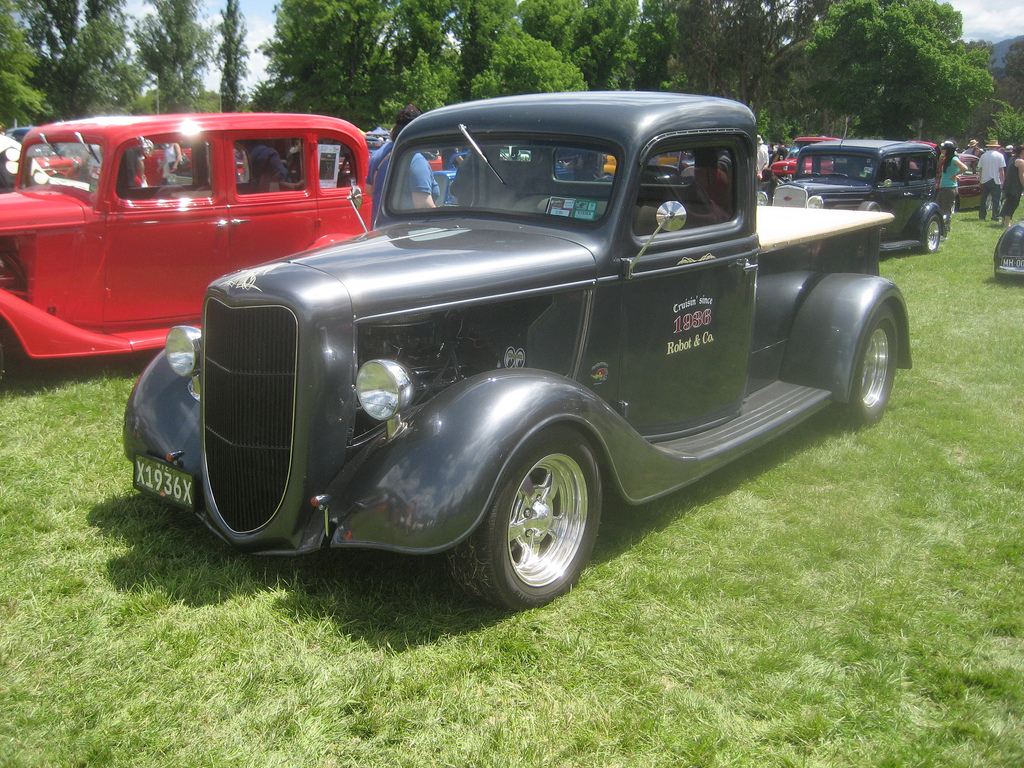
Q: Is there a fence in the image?
A: No, there are no fences.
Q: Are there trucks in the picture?
A: Yes, there is a truck.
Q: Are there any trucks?
A: Yes, there is a truck.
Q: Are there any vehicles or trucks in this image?
A: Yes, there is a truck.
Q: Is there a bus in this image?
A: No, there are no buses.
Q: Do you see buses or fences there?
A: No, there are no buses or fences.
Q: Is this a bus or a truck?
A: This is a truck.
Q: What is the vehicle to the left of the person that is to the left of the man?
A: The vehicle is a truck.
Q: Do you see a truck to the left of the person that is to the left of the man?
A: Yes, there is a truck to the left of the person.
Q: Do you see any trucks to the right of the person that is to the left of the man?
A: No, the truck is to the left of the person.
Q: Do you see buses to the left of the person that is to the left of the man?
A: No, there is a truck to the left of the person.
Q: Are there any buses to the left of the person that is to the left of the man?
A: No, there is a truck to the left of the person.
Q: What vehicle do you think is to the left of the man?
A: The vehicle is a truck.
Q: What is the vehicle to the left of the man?
A: The vehicle is a truck.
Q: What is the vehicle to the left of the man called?
A: The vehicle is a truck.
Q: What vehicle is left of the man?
A: The vehicle is a truck.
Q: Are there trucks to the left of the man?
A: Yes, there is a truck to the left of the man.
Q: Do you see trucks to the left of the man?
A: Yes, there is a truck to the left of the man.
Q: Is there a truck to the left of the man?
A: Yes, there is a truck to the left of the man.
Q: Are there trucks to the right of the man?
A: No, the truck is to the left of the man.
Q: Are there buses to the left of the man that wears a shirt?
A: No, there is a truck to the left of the man.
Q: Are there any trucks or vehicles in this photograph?
A: Yes, there is a truck.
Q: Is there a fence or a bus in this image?
A: No, there are no fences or buses.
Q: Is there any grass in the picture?
A: Yes, there is grass.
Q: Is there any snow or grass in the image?
A: Yes, there is grass.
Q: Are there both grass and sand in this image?
A: No, there is grass but no sand.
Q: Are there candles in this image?
A: No, there are no candles.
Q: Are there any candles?
A: No, there are no candles.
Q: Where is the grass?
A: The grass is on the ground.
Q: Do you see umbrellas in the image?
A: No, there are no umbrellas.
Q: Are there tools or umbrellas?
A: No, there are no umbrellas or tools.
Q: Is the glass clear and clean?
A: Yes, the glass is clear and clean.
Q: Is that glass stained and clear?
A: No, the glass is clear but clean.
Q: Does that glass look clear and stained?
A: No, the glass is clear but clean.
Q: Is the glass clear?
A: Yes, the glass is clear.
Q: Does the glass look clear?
A: Yes, the glass is clear.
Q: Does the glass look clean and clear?
A: Yes, the glass is clean and clear.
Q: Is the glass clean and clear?
A: Yes, the glass is clean and clear.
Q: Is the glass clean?
A: Yes, the glass is clean.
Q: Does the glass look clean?
A: Yes, the glass is clean.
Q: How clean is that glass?
A: The glass is clean.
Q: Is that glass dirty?
A: No, the glass is clean.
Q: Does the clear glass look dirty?
A: No, the glass is clean.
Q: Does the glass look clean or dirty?
A: The glass is clean.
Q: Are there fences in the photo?
A: No, there are no fences.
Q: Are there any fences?
A: No, there are no fences.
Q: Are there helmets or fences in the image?
A: No, there are no fences or helmets.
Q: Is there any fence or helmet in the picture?
A: No, there are no fences or helmets.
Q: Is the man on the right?
A: Yes, the man is on the right of the image.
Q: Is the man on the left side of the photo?
A: No, the man is on the right of the image.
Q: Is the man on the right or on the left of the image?
A: The man is on the right of the image.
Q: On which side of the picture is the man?
A: The man is on the right of the image.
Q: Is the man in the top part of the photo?
A: Yes, the man is in the top of the image.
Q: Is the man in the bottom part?
A: No, the man is in the top of the image.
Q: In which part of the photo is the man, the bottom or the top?
A: The man is in the top of the image.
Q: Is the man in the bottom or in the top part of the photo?
A: The man is in the top of the image.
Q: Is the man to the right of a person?
A: Yes, the man is to the right of a person.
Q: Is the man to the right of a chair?
A: No, the man is to the right of a person.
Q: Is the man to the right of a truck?
A: Yes, the man is to the right of a truck.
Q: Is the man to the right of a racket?
A: No, the man is to the right of a truck.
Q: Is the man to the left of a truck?
A: No, the man is to the right of a truck.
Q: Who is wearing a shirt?
A: The man is wearing a shirt.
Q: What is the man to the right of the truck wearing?
A: The man is wearing a shirt.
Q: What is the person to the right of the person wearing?
A: The man is wearing a shirt.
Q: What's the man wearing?
A: The man is wearing a shirt.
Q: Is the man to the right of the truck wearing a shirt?
A: Yes, the man is wearing a shirt.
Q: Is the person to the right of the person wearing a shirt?
A: Yes, the man is wearing a shirt.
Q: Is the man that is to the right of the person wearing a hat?
A: No, the man is wearing a shirt.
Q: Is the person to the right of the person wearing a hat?
A: No, the man is wearing a shirt.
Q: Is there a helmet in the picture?
A: No, there are no helmets.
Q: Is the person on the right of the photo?
A: Yes, the person is on the right of the image.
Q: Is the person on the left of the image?
A: No, the person is on the right of the image.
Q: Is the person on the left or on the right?
A: The person is on the right of the image.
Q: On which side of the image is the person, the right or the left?
A: The person is on the right of the image.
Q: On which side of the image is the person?
A: The person is on the right of the image.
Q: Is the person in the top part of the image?
A: Yes, the person is in the top of the image.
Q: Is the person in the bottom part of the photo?
A: No, the person is in the top of the image.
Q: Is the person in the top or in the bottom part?
A: The person is in the top of the image.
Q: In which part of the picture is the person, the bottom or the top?
A: The person is in the top of the image.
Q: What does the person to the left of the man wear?
A: The person wears a shirt.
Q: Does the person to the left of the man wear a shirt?
A: Yes, the person wears a shirt.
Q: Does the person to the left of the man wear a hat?
A: No, the person wears a shirt.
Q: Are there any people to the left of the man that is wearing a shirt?
A: Yes, there is a person to the left of the man.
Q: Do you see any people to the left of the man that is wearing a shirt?
A: Yes, there is a person to the left of the man.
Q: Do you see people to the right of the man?
A: No, the person is to the left of the man.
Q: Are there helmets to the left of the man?
A: No, there is a person to the left of the man.